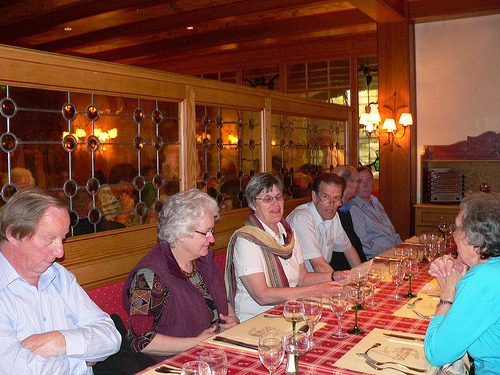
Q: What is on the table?
A: Glasses.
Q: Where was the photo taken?
A: In a restaurant.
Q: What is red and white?
A: Tablecloth.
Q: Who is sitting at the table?
A: People.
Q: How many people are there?
A: Seven.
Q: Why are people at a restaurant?
A: To eat.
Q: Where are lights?
A: On the wall.